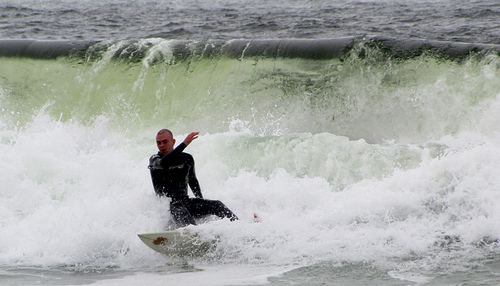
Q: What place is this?
A: It is an ocean.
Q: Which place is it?
A: It is an ocean.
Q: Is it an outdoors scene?
A: Yes, it is outdoors.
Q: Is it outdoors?
A: Yes, it is outdoors.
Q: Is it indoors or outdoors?
A: It is outdoors.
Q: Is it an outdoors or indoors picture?
A: It is outdoors.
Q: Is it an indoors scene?
A: No, it is outdoors.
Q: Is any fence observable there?
A: No, there are no fences.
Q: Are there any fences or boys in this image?
A: No, there are no fences or boys.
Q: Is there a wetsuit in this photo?
A: Yes, there is a wetsuit.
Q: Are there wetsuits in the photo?
A: Yes, there is a wetsuit.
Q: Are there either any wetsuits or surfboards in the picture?
A: Yes, there is a wetsuit.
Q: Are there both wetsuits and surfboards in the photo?
A: Yes, there are both a wetsuit and a surfboard.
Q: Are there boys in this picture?
A: No, there are no boys.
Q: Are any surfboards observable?
A: Yes, there is a surfboard.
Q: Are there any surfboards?
A: Yes, there is a surfboard.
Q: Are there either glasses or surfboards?
A: Yes, there is a surfboard.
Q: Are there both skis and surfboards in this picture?
A: No, there is a surfboard but no skis.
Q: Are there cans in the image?
A: No, there are no cans.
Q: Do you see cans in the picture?
A: No, there are no cans.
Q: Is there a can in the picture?
A: No, there are no cans.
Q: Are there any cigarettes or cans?
A: No, there are no cans or cigarettes.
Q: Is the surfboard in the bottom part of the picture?
A: Yes, the surfboard is in the bottom of the image.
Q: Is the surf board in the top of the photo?
A: No, the surf board is in the bottom of the image.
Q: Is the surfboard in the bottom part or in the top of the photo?
A: The surfboard is in the bottom of the image.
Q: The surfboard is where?
A: The surfboard is in the water.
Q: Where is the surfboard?
A: The surfboard is in the water.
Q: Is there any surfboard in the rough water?
A: Yes, there is a surfboard in the water.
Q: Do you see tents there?
A: No, there are no tents.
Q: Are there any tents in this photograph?
A: No, there are no tents.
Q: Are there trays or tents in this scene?
A: No, there are no tents or trays.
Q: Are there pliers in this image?
A: No, there are no pliers.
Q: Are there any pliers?
A: No, there are no pliers.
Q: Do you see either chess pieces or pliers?
A: No, there are no pliers or chess pieces.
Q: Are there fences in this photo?
A: No, there are no fences.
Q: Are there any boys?
A: No, there are no boys.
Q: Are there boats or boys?
A: No, there are no boys or boats.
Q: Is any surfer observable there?
A: Yes, there is a surfer.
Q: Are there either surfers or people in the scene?
A: Yes, there is a surfer.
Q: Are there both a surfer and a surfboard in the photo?
A: Yes, there are both a surfer and a surfboard.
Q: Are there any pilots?
A: No, there are no pilots.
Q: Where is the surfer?
A: The surfer is in the ocean.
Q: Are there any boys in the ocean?
A: No, there is a surfer in the ocean.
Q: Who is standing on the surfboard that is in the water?
A: The surfer is standing on the surfboard.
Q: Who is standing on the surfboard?
A: The surfer is standing on the surfboard.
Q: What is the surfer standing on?
A: The surfer is standing on the surfboard.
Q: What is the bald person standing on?
A: The surfer is standing on the surfboard.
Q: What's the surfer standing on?
A: The surfer is standing on the surfboard.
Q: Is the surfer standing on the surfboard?
A: Yes, the surfer is standing on the surfboard.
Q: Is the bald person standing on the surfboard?
A: Yes, the surfer is standing on the surfboard.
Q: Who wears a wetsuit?
A: The surfer wears a wetsuit.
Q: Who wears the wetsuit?
A: The surfer wears a wetsuit.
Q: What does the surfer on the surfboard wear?
A: The surfer wears a wetsuit.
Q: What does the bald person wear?
A: The surfer wears a wetsuit.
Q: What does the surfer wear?
A: The surfer wears a wetsuit.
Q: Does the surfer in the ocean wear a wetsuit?
A: Yes, the surfer wears a wetsuit.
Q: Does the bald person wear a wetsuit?
A: Yes, the surfer wears a wetsuit.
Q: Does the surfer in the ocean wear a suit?
A: No, the surfer wears a wetsuit.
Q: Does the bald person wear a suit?
A: No, the surfer wears a wetsuit.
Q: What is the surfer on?
A: The surfer is on the surfboard.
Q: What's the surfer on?
A: The surfer is on the surfboard.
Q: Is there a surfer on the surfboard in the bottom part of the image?
A: Yes, there is a surfer on the surfboard.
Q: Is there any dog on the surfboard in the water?
A: No, there is a surfer on the surfboard.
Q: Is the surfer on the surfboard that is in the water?
A: Yes, the surfer is on the surf board.